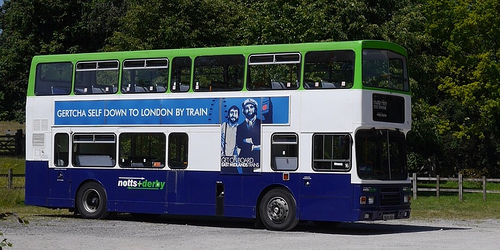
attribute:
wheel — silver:
[254, 182, 301, 233]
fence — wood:
[0, 163, 498, 200]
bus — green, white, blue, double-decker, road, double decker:
[23, 38, 416, 231]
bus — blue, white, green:
[21, 43, 423, 206]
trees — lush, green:
[419, 49, 494, 149]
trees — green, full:
[12, 2, 499, 181]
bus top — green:
[27, 40, 415, 95]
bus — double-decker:
[13, 31, 422, 238]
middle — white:
[22, 96, 411, 170]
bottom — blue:
[21, 164, 417, 229]